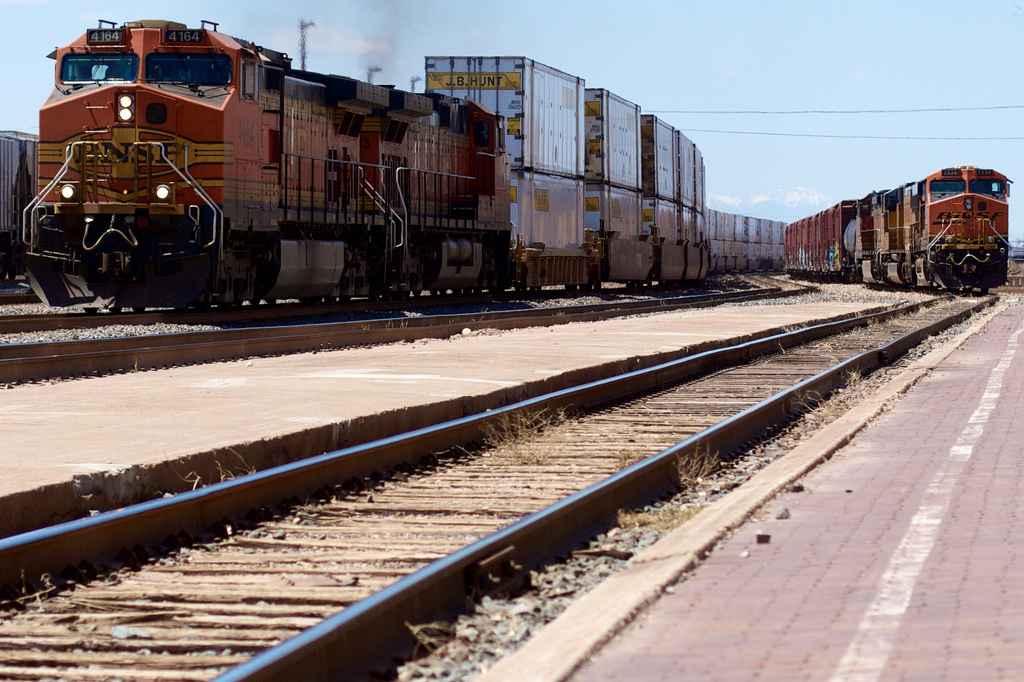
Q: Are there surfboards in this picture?
A: No, there are no surfboards.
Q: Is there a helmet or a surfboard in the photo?
A: No, there are no surfboards or helmets.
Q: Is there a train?
A: Yes, there is a train.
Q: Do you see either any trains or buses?
A: Yes, there is a train.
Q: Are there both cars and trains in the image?
A: Yes, there are both a train and cars.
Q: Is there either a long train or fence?
A: Yes, there is a long train.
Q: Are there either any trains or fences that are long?
A: Yes, the train is long.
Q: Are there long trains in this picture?
A: Yes, there is a long train.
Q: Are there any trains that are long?
A: Yes, there is a train that is long.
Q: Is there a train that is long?
A: Yes, there is a train that is long.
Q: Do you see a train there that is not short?
A: Yes, there is a long train.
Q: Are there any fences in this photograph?
A: No, there are no fences.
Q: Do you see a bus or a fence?
A: No, there are no fences or buses.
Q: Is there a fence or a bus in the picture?
A: No, there are no fences or buses.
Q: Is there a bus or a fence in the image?
A: No, there are no fences or buses.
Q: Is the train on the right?
A: Yes, the train is on the right of the image.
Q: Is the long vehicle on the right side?
A: Yes, the train is on the right of the image.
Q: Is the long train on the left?
A: No, the train is on the right of the image.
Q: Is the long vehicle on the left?
A: No, the train is on the right of the image.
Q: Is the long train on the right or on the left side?
A: The train is on the right of the image.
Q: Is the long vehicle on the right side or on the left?
A: The train is on the right of the image.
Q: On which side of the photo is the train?
A: The train is on the right of the image.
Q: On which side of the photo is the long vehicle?
A: The train is on the right of the image.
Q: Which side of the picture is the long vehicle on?
A: The train is on the right of the image.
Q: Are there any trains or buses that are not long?
A: No, there is a train but it is long.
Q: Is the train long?
A: Yes, the train is long.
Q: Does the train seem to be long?
A: Yes, the train is long.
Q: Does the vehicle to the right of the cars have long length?
A: Yes, the train is long.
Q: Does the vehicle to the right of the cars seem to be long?
A: Yes, the train is long.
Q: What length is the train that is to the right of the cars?
A: The train is long.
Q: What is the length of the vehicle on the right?
A: The train is long.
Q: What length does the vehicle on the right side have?
A: The train has long length.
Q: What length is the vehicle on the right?
A: The train is long.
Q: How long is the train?
A: The train is long.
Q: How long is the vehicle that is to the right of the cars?
A: The train is long.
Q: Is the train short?
A: No, the train is long.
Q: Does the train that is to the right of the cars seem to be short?
A: No, the train is long.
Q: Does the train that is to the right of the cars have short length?
A: No, the train is long.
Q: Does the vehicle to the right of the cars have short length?
A: No, the train is long.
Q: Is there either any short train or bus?
A: No, there is a train but it is long.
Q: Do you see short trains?
A: No, there is a train but it is long.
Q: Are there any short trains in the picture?
A: No, there is a train but it is long.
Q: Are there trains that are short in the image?
A: No, there is a train but it is long.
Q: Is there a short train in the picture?
A: No, there is a train but it is long.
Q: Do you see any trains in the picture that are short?
A: No, there is a train but it is long.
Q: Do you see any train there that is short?
A: No, there is a train but it is long.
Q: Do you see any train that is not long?
A: No, there is a train but it is long.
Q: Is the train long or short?
A: The train is long.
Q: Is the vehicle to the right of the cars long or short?
A: The train is long.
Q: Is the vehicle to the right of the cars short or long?
A: The train is long.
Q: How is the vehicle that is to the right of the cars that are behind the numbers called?
A: The vehicle is a train.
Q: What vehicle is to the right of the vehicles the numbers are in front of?
A: The vehicle is a train.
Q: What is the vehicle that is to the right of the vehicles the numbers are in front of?
A: The vehicle is a train.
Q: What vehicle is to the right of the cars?
A: The vehicle is a train.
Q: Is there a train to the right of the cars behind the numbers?
A: Yes, there is a train to the right of the cars.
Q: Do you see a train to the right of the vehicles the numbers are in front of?
A: Yes, there is a train to the right of the cars.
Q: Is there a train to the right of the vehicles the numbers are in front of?
A: Yes, there is a train to the right of the cars.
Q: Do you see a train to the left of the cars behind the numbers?
A: No, the train is to the right of the cars.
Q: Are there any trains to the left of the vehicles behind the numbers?
A: No, the train is to the right of the cars.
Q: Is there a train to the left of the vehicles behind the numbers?
A: No, the train is to the right of the cars.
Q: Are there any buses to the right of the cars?
A: No, there is a train to the right of the cars.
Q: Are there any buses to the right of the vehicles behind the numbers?
A: No, there is a train to the right of the cars.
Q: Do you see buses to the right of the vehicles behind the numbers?
A: No, there is a train to the right of the cars.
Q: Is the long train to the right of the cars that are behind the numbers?
A: Yes, the train is to the right of the cars.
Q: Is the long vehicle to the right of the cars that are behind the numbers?
A: Yes, the train is to the right of the cars.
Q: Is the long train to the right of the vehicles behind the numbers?
A: Yes, the train is to the right of the cars.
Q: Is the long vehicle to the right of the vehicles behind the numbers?
A: Yes, the train is to the right of the cars.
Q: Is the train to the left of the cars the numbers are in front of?
A: No, the train is to the right of the cars.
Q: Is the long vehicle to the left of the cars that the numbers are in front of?
A: No, the train is to the right of the cars.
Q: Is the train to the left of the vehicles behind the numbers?
A: No, the train is to the right of the cars.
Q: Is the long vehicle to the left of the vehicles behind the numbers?
A: No, the train is to the right of the cars.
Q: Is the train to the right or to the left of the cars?
A: The train is to the right of the cars.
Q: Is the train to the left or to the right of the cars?
A: The train is to the right of the cars.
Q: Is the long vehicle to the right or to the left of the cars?
A: The train is to the right of the cars.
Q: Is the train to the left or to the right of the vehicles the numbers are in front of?
A: The train is to the right of the cars.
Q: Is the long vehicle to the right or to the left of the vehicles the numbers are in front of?
A: The train is to the right of the cars.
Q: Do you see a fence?
A: No, there are no fences.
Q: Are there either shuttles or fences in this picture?
A: No, there are no fences or shuttles.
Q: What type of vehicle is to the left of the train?
A: The vehicles are cars.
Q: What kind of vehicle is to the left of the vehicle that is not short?
A: The vehicles are cars.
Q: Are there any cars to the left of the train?
A: Yes, there are cars to the left of the train.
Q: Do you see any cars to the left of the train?
A: Yes, there are cars to the left of the train.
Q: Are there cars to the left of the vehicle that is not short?
A: Yes, there are cars to the left of the train.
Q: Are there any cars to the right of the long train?
A: No, the cars are to the left of the train.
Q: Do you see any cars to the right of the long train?
A: No, the cars are to the left of the train.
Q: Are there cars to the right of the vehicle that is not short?
A: No, the cars are to the left of the train.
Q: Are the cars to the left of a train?
A: Yes, the cars are to the left of a train.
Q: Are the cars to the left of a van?
A: No, the cars are to the left of a train.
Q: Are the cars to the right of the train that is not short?
A: No, the cars are to the left of the train.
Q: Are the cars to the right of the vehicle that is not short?
A: No, the cars are to the left of the train.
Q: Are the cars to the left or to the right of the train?
A: The cars are to the left of the train.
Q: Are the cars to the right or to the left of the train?
A: The cars are to the left of the train.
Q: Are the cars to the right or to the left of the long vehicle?
A: The cars are to the left of the train.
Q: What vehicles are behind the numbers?
A: The vehicles are cars.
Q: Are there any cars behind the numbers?
A: Yes, there are cars behind the numbers.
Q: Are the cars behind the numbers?
A: Yes, the cars are behind the numbers.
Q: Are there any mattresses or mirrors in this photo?
A: No, there are no mirrors or mattresses.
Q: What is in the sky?
A: The clouds are in the sky.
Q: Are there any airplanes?
A: No, there are no airplanes.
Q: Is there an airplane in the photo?
A: No, there are no airplanes.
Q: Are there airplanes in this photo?
A: No, there are no airplanes.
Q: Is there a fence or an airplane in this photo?
A: No, there are no airplanes or fences.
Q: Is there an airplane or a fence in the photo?
A: No, there are no airplanes or fences.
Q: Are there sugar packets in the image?
A: No, there are no sugar packets.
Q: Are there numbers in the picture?
A: Yes, there are numbers.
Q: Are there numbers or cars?
A: Yes, there are numbers.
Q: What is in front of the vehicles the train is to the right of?
A: The numbers are in front of the cars.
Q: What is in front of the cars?
A: The numbers are in front of the cars.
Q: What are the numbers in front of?
A: The numbers are in front of the cars.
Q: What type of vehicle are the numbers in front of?
A: The numbers are in front of the cars.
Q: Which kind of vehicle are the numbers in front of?
A: The numbers are in front of the cars.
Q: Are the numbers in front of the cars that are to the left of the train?
A: Yes, the numbers are in front of the cars.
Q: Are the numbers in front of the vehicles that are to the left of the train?
A: Yes, the numbers are in front of the cars.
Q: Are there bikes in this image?
A: No, there are no bikes.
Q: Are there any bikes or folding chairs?
A: No, there are no bikes or folding chairs.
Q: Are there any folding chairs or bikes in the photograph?
A: No, there are no bikes or folding chairs.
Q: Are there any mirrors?
A: No, there are no mirrors.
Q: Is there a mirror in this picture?
A: No, there are no mirrors.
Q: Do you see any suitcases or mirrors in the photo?
A: No, there are no mirrors or suitcases.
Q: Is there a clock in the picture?
A: No, there are no clocks.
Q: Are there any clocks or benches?
A: No, there are no clocks or benches.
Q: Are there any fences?
A: No, there are no fences.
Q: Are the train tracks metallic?
A: Yes, the train tracks are metallic.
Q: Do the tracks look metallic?
A: Yes, the tracks are metallic.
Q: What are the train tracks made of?
A: The train tracks are made of metal.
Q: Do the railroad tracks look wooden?
A: No, the railroad tracks are metallic.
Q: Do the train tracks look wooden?
A: No, the train tracks are metallic.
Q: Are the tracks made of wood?
A: No, the tracks are made of metal.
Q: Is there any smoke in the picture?
A: Yes, there is smoke.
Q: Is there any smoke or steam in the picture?
A: Yes, there is smoke.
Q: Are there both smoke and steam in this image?
A: No, there is smoke but no steam.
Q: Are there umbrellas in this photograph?
A: No, there are no umbrellas.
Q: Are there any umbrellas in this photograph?
A: No, there are no umbrellas.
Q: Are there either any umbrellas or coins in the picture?
A: No, there are no umbrellas or coins.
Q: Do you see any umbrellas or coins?
A: No, there are no umbrellas or coins.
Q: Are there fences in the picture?
A: No, there are no fences.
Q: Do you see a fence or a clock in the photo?
A: No, there are no fences or clocks.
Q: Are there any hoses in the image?
A: No, there are no hoses.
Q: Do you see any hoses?
A: No, there are no hoses.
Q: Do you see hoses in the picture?
A: No, there are no hoses.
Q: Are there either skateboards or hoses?
A: No, there are no hoses or skateboards.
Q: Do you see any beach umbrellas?
A: No, there are no beach umbrellas.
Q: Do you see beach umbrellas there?
A: No, there are no beach umbrellas.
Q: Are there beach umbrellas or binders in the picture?
A: No, there are no beach umbrellas or binders.